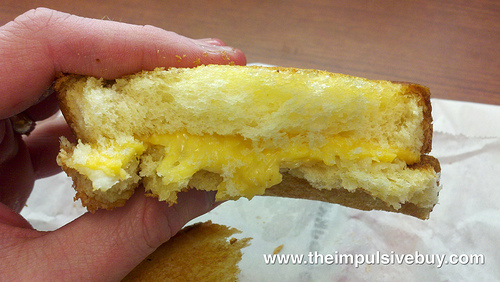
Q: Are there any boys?
A: No, there are no boys.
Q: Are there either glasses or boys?
A: No, there are no boys or glasses.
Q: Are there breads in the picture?
A: Yes, there is a bread.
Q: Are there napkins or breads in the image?
A: Yes, there is a bread.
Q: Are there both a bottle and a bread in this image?
A: No, there is a bread but no bottles.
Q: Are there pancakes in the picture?
A: No, there are no pancakes.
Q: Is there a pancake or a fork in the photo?
A: No, there are no pancakes or forks.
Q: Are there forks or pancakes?
A: No, there are no pancakes or forks.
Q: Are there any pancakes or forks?
A: No, there are no pancakes or forks.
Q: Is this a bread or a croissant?
A: This is a bread.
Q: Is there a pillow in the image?
A: No, there are no pillows.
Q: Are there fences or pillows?
A: No, there are no pillows or fences.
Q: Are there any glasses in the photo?
A: No, there are no glasses.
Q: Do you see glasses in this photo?
A: No, there are no glasses.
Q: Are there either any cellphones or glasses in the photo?
A: No, there are no glasses or cellphones.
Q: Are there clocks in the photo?
A: No, there are no clocks.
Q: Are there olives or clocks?
A: No, there are no clocks or olives.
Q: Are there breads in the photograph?
A: Yes, there is a bread.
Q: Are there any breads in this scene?
A: Yes, there is a bread.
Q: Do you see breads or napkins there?
A: Yes, there is a bread.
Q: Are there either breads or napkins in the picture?
A: Yes, there is a bread.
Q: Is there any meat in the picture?
A: No, there is no meat.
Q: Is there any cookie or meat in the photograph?
A: No, there are no meat or cookies.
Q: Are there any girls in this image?
A: No, there are no girls.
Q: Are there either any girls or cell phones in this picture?
A: No, there are no girls or cell phones.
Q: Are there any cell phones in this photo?
A: No, there are no cell phones.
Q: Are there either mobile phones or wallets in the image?
A: No, there are no mobile phones or wallets.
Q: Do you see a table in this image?
A: Yes, there is a table.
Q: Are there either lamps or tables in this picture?
A: Yes, there is a table.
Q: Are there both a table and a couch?
A: No, there is a table but no couches.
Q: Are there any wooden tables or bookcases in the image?
A: Yes, there is a wood table.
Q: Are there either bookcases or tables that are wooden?
A: Yes, the table is wooden.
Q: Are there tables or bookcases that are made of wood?
A: Yes, the table is made of wood.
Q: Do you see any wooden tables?
A: Yes, there is a wood table.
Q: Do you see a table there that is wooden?
A: Yes, there is a table that is wooden.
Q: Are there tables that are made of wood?
A: Yes, there is a table that is made of wood.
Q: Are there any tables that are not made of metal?
A: Yes, there is a table that is made of wood.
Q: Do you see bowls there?
A: No, there are no bowls.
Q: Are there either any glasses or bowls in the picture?
A: No, there are no bowls or glasses.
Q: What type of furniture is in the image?
A: The furniture is a table.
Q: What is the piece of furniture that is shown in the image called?
A: The piece of furniture is a table.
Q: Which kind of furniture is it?
A: The piece of furniture is a table.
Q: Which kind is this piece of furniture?
A: This is a table.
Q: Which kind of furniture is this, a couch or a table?
A: This is a table.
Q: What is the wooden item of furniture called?
A: The piece of furniture is a table.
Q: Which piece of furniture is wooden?
A: The piece of furniture is a table.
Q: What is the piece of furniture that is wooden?
A: The piece of furniture is a table.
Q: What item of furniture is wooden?
A: The piece of furniture is a table.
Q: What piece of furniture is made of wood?
A: The piece of furniture is a table.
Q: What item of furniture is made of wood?
A: The piece of furniture is a table.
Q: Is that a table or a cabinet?
A: That is a table.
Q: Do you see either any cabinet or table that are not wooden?
A: No, there is a table but it is wooden.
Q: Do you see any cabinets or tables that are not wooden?
A: No, there is a table but it is wooden.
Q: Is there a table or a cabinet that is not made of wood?
A: No, there is a table but it is made of wood.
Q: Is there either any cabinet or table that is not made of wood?
A: No, there is a table but it is made of wood.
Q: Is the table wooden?
A: Yes, the table is wooden.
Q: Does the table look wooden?
A: Yes, the table is wooden.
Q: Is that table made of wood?
A: Yes, the table is made of wood.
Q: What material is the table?
A: The table is made of wood.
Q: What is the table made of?
A: The table is made of wood.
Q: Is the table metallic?
A: No, the table is wooden.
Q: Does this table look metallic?
A: No, the table is wooden.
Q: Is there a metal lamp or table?
A: No, there is a table but it is wooden.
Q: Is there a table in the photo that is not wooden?
A: No, there is a table but it is wooden.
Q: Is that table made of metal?
A: No, the table is made of wood.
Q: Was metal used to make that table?
A: No, the table is made of wood.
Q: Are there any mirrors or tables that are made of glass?
A: No, there is a table but it is made of wood.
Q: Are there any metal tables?
A: No, there is a table but it is made of wood.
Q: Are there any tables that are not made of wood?
A: No, there is a table but it is made of wood.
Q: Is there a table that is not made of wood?
A: No, there is a table but it is made of wood.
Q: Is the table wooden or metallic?
A: The table is wooden.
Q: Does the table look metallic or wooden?
A: The table is wooden.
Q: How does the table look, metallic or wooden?
A: The table is wooden.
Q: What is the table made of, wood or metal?
A: The table is made of wood.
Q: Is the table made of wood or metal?
A: The table is made of wood.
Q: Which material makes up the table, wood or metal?
A: The table is made of wood.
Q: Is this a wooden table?
A: Yes, this is a wooden table.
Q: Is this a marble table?
A: No, this is a wooden table.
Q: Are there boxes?
A: No, there are no boxes.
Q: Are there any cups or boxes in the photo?
A: No, there are no boxes or cups.